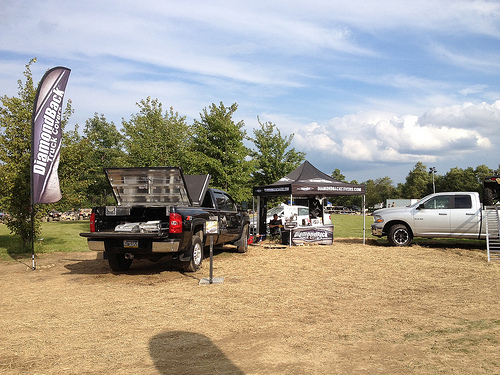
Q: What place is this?
A: It is a field.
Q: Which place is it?
A: It is a field.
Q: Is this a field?
A: Yes, it is a field.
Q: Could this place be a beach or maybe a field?
A: It is a field.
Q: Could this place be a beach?
A: No, it is a field.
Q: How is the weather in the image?
A: It is cloudy.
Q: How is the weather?
A: It is cloudy.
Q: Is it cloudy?
A: Yes, it is cloudy.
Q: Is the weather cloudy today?
A: Yes, it is cloudy.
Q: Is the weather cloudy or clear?
A: It is cloudy.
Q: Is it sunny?
A: No, it is cloudy.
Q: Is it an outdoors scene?
A: Yes, it is outdoors.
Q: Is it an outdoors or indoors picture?
A: It is outdoors.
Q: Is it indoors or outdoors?
A: It is outdoors.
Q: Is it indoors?
A: No, it is outdoors.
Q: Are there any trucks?
A: Yes, there is a truck.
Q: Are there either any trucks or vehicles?
A: Yes, there is a truck.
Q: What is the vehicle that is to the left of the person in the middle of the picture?
A: The vehicle is a truck.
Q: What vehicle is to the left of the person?
A: The vehicle is a truck.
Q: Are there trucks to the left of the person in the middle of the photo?
A: Yes, there is a truck to the left of the person.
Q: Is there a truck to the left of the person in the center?
A: Yes, there is a truck to the left of the person.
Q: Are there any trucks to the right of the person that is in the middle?
A: No, the truck is to the left of the person.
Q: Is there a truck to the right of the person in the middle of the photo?
A: No, the truck is to the left of the person.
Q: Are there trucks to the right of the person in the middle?
A: No, the truck is to the left of the person.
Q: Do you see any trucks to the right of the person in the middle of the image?
A: No, the truck is to the left of the person.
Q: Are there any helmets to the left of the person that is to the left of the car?
A: No, there is a truck to the left of the person.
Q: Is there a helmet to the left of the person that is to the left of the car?
A: No, there is a truck to the left of the person.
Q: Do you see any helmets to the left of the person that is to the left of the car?
A: No, there is a truck to the left of the person.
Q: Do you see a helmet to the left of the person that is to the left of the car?
A: No, there is a truck to the left of the person.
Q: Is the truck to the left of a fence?
A: No, the truck is to the left of a person.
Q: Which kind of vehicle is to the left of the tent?
A: The vehicle is a truck.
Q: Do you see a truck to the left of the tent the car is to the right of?
A: Yes, there is a truck to the left of the tent.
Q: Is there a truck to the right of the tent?
A: No, the truck is to the left of the tent.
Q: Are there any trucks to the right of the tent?
A: No, the truck is to the left of the tent.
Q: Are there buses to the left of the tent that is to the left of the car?
A: No, there is a truck to the left of the tent.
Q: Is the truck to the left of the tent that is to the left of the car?
A: Yes, the truck is to the left of the tent.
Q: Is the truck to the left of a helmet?
A: No, the truck is to the left of the tent.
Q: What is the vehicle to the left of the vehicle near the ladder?
A: The vehicle is a truck.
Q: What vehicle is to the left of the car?
A: The vehicle is a truck.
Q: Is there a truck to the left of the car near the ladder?
A: Yes, there is a truck to the left of the car.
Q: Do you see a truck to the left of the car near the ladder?
A: Yes, there is a truck to the left of the car.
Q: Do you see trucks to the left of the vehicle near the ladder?
A: Yes, there is a truck to the left of the car.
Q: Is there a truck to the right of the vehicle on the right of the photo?
A: No, the truck is to the left of the car.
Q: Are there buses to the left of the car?
A: No, there is a truck to the left of the car.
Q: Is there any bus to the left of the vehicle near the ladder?
A: No, there is a truck to the left of the car.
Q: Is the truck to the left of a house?
A: No, the truck is to the left of a car.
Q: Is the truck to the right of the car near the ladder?
A: No, the truck is to the left of the car.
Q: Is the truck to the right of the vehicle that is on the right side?
A: No, the truck is to the left of the car.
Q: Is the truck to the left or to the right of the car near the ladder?
A: The truck is to the left of the car.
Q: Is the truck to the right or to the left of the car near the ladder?
A: The truck is to the left of the car.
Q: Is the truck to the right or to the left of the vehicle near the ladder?
A: The truck is to the left of the car.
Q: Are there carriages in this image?
A: No, there are no carriages.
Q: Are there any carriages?
A: No, there are no carriages.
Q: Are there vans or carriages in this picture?
A: No, there are no carriages or vans.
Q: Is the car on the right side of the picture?
A: Yes, the car is on the right of the image.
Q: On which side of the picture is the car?
A: The car is on the right of the image.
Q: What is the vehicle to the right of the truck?
A: The vehicle is a car.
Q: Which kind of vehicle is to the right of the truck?
A: The vehicle is a car.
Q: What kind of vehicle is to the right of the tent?
A: The vehicle is a car.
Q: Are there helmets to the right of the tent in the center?
A: No, there is a car to the right of the tent.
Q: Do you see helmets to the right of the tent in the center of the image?
A: No, there is a car to the right of the tent.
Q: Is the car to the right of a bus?
A: No, the car is to the right of the tent.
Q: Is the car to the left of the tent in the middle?
A: No, the car is to the right of the tent.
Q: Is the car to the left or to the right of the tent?
A: The car is to the right of the tent.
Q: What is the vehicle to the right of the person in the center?
A: The vehicle is a car.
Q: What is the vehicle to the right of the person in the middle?
A: The vehicle is a car.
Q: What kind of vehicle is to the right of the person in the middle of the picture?
A: The vehicle is a car.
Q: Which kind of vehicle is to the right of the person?
A: The vehicle is a car.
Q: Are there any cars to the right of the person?
A: Yes, there is a car to the right of the person.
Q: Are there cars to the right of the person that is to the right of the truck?
A: Yes, there is a car to the right of the person.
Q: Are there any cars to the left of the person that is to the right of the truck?
A: No, the car is to the right of the person.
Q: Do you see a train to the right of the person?
A: No, there is a car to the right of the person.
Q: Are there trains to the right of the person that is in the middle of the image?
A: No, there is a car to the right of the person.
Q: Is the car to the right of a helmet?
A: No, the car is to the right of a person.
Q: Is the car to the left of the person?
A: No, the car is to the right of the person.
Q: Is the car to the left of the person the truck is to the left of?
A: No, the car is to the right of the person.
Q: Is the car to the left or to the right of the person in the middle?
A: The car is to the right of the person.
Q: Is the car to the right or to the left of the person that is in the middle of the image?
A: The car is to the right of the person.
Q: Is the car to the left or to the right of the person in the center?
A: The car is to the right of the person.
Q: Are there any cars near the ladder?
A: Yes, there is a car near the ladder.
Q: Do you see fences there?
A: No, there are no fences.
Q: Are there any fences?
A: No, there are no fences.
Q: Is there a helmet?
A: No, there are no helmets.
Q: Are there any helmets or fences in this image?
A: No, there are no helmets or fences.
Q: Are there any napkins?
A: No, there are no napkins.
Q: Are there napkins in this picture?
A: No, there are no napkins.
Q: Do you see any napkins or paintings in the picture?
A: No, there are no napkins or paintings.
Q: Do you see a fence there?
A: No, there are no fences.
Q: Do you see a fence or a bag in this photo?
A: No, there are no fences or bags.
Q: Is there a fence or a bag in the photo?
A: No, there are no fences or bags.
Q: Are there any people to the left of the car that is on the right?
A: Yes, there is a person to the left of the car.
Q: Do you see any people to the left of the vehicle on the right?
A: Yes, there is a person to the left of the car.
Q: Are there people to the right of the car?
A: No, the person is to the left of the car.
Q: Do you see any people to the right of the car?
A: No, the person is to the left of the car.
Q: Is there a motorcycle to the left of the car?
A: No, there is a person to the left of the car.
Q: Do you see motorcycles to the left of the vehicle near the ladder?
A: No, there is a person to the left of the car.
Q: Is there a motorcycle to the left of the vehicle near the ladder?
A: No, there is a person to the left of the car.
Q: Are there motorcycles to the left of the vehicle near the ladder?
A: No, there is a person to the left of the car.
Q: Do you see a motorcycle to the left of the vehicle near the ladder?
A: No, there is a person to the left of the car.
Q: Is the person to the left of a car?
A: Yes, the person is to the left of a car.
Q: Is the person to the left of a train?
A: No, the person is to the left of a car.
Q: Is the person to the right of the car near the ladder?
A: No, the person is to the left of the car.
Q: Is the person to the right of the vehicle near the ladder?
A: No, the person is to the left of the car.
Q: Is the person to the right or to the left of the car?
A: The person is to the left of the car.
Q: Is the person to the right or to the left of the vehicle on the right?
A: The person is to the left of the car.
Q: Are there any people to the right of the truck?
A: Yes, there is a person to the right of the truck.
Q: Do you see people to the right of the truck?
A: Yes, there is a person to the right of the truck.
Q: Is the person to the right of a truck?
A: Yes, the person is to the right of a truck.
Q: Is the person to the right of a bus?
A: No, the person is to the right of a truck.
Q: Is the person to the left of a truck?
A: No, the person is to the right of a truck.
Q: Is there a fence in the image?
A: No, there are no fences.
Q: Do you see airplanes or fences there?
A: No, there are no fences or airplanes.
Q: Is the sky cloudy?
A: Yes, the sky is cloudy.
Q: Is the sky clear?
A: No, the sky is cloudy.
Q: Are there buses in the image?
A: No, there are no buses.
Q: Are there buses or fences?
A: No, there are no buses or fences.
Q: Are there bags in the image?
A: No, there are no bags.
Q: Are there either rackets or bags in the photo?
A: No, there are no bags or rackets.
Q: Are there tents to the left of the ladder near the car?
A: Yes, there is a tent to the left of the ladder.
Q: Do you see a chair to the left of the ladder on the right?
A: No, there is a tent to the left of the ladder.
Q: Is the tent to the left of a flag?
A: No, the tent is to the left of the ladder.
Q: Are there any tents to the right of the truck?
A: Yes, there is a tent to the right of the truck.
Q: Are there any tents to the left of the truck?
A: No, the tent is to the right of the truck.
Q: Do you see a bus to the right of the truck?
A: No, there is a tent to the right of the truck.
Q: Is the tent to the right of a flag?
A: No, the tent is to the right of the truck.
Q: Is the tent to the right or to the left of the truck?
A: The tent is to the right of the truck.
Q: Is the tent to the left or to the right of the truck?
A: The tent is to the right of the truck.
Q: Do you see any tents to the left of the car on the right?
A: Yes, there is a tent to the left of the car.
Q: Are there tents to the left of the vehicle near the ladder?
A: Yes, there is a tent to the left of the car.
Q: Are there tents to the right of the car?
A: No, the tent is to the left of the car.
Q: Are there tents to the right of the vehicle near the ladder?
A: No, the tent is to the left of the car.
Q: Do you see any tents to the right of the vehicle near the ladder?
A: No, the tent is to the left of the car.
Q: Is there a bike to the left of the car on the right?
A: No, there is a tent to the left of the car.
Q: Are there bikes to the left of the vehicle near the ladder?
A: No, there is a tent to the left of the car.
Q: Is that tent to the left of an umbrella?
A: No, the tent is to the left of the car.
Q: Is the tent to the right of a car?
A: No, the tent is to the left of a car.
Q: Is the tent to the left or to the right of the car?
A: The tent is to the left of the car.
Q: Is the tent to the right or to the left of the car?
A: The tent is to the left of the car.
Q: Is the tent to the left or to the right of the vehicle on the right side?
A: The tent is to the left of the car.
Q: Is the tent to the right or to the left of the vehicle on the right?
A: The tent is to the left of the car.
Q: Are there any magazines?
A: No, there are no magazines.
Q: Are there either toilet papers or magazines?
A: No, there are no magazines or toilet papers.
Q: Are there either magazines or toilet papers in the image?
A: No, there are no magazines or toilet papers.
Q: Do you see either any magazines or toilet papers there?
A: No, there are no magazines or toilet papers.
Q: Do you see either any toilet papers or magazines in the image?
A: No, there are no magazines or toilet papers.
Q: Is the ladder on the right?
A: Yes, the ladder is on the right of the image.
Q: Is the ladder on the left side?
A: No, the ladder is on the right of the image.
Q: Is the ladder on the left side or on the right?
A: The ladder is on the right of the image.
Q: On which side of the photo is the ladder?
A: The ladder is on the right of the image.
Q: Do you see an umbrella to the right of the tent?
A: No, there is a ladder to the right of the tent.